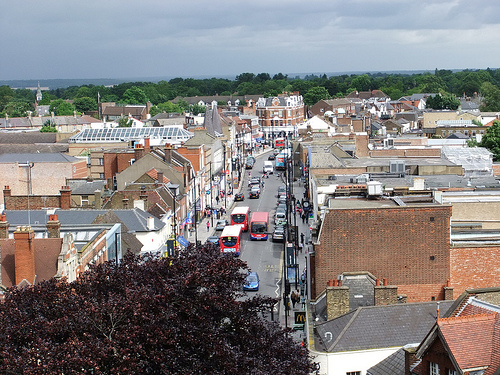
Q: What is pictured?
A: An aerial view of a city.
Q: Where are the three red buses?
A: Middle of the picture in the street.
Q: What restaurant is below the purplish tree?
A: McDonalds.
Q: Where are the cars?
A: In the street.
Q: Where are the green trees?
A: Just beyond the houses and buildings.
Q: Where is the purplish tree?
A: Bottom left.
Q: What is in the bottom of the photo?
A: A tree.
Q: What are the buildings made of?
A: Brick.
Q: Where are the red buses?
A: The street.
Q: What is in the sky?
A: Clouds.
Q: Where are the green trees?
A: In the distance.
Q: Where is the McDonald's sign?
A: At the bottom.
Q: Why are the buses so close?
A: The street is narrow.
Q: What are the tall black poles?
A: Street lights.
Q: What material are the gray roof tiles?
A: Stone or slate.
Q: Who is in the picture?
A: No indication of who.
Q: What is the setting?
A: City.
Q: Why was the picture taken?
A: Area view.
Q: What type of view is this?
A: Aerial.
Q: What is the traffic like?
A: Busy.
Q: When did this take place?
A: Daytime.